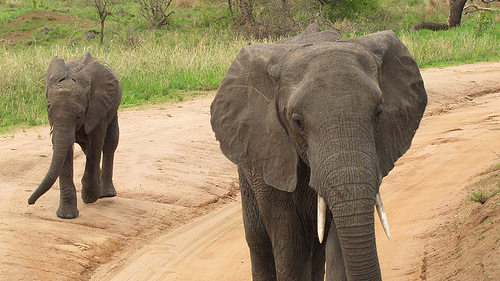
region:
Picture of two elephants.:
[26, 20, 436, 275]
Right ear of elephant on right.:
[200, 20, 295, 195]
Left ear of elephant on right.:
[380, 15, 425, 180]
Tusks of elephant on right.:
[305, 165, 390, 245]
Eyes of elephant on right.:
[280, 81, 390, 126]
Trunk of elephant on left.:
[25, 116, 71, 206]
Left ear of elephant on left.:
[83, 50, 120, 139]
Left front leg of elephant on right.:
[83, 125, 111, 217]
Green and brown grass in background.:
[125, 35, 210, 86]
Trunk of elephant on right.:
[308, 148, 400, 279]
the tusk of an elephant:
[313, 192, 330, 243]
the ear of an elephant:
[207, 36, 301, 196]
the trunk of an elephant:
[24, 124, 78, 207]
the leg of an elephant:
[53, 142, 81, 219]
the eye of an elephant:
[290, 112, 307, 132]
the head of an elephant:
[206, 27, 429, 199]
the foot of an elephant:
[53, 200, 80, 222]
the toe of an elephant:
[65, 211, 74, 220]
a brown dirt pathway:
[1, 59, 498, 279]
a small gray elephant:
[19, 53, 121, 225]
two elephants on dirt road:
[25, 22, 454, 252]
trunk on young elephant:
[25, 133, 77, 215]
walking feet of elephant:
[56, 172, 116, 231]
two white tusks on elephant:
[303, 182, 394, 256]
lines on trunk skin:
[348, 185, 370, 259]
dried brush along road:
[151, 42, 208, 93]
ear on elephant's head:
[373, 26, 430, 171]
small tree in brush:
[90, 5, 113, 48]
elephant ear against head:
[40, 53, 62, 100]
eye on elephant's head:
[289, 109, 308, 135]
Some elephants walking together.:
[10, 8, 442, 263]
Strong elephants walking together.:
[0, 23, 465, 259]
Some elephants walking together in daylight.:
[11, 8, 448, 263]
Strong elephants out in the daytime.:
[30, 0, 460, 260]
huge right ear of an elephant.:
[204, 46, 290, 209]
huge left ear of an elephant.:
[376, 22, 444, 172]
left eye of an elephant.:
[370, 96, 395, 146]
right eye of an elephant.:
[285, 105, 310, 140]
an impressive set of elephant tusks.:
[309, 182, 401, 248]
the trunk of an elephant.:
[12, 122, 72, 207]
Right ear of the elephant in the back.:
[81, 64, 118, 137]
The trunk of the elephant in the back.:
[25, 136, 65, 208]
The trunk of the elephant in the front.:
[332, 192, 385, 279]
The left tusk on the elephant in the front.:
[313, 195, 330, 243]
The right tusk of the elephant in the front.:
[367, 187, 397, 235]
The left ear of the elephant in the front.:
[207, 45, 305, 196]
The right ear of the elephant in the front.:
[366, 31, 427, 166]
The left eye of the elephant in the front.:
[291, 103, 305, 131]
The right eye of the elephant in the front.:
[367, 94, 387, 127]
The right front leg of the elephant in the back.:
[80, 127, 110, 203]